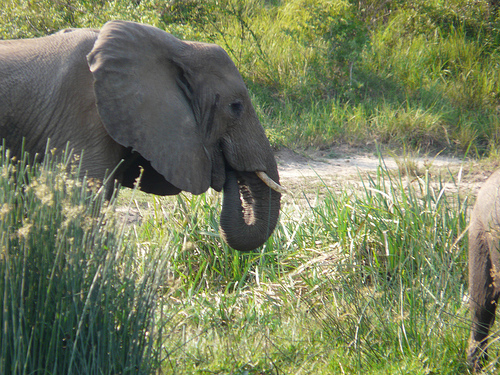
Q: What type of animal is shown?
A: Elephant.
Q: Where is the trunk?
A: Mouth.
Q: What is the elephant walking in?
A: Tall grass.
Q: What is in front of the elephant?
A: Another elephant.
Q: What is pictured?
A: Elephants.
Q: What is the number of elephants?
A: Two.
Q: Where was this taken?
A: Grassy field.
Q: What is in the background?
A: Foliage.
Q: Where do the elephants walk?
A: In tall grass.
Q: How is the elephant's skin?
A: Grey and wrinkled.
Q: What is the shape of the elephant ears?
A: Trapezoidal and rounded.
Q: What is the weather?
A: Sunny.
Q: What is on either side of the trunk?
A: Tusks.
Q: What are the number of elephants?
A: Two.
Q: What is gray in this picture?
A: The elephant is gray.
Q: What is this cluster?
A: The cluster is of green grass.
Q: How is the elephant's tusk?
A: The elephant's tusk is upturned.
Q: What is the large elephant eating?
A: The large elephant is eating grass.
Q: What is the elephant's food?
A: The long green grass is the elephants food.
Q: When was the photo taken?
A: Daytime.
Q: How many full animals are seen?
A: One.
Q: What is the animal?
A: An elephant.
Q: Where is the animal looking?
A: To the right.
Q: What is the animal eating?
A: Grass.